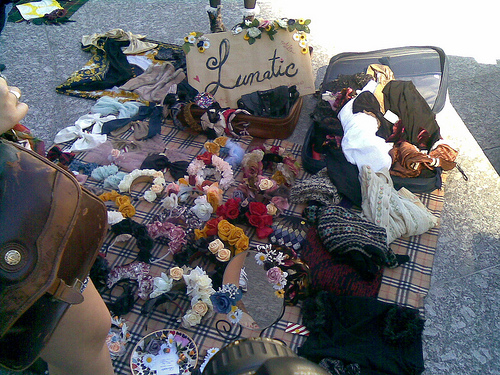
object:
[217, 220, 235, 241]
roses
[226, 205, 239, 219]
roses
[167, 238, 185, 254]
roses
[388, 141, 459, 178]
scarf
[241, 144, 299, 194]
headband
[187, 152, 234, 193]
headband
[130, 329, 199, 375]
plate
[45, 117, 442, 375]
blanket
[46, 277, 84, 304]
strap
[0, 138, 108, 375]
bag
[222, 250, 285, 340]
mirror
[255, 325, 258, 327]
toes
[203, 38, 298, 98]
sign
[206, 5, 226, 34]
boots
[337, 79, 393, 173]
cloths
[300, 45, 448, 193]
suitcase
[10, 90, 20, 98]
ring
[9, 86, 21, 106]
finger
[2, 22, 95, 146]
ground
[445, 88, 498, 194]
curb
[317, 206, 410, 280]
clothes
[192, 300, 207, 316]
flowers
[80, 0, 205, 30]
sidewalk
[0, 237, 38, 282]
button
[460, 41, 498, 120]
road